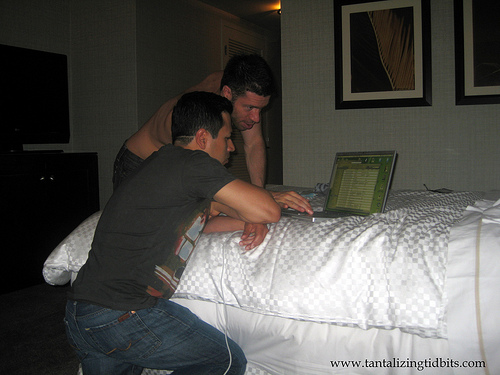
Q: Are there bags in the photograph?
A: No, there are no bags.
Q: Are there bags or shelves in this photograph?
A: No, there are no bags or shelves.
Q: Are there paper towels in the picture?
A: No, there are no paper towels.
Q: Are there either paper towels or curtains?
A: No, there are no paper towels or curtains.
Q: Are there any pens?
A: No, there are no pens.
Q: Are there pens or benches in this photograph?
A: No, there are no pens or benches.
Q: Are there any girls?
A: No, there are no girls.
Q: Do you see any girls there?
A: No, there are no girls.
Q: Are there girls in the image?
A: No, there are no girls.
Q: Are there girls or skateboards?
A: No, there are no girls or skateboards.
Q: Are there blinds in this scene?
A: No, there are no blinds.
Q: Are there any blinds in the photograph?
A: No, there are no blinds.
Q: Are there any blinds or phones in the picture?
A: No, there are no blinds or phones.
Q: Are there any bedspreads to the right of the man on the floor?
A: Yes, there is a bedspread to the right of the man.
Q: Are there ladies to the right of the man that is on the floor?
A: No, there is a bedspread to the right of the man.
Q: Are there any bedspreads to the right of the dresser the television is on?
A: Yes, there is a bedspread to the right of the dresser.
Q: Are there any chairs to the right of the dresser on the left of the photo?
A: No, there is a bedspread to the right of the dresser.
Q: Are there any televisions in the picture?
A: Yes, there is a television.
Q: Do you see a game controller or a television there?
A: Yes, there is a television.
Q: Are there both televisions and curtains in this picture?
A: No, there is a television but no curtains.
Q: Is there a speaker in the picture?
A: No, there are no speakers.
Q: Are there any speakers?
A: No, there are no speakers.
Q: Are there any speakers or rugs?
A: No, there are no speakers or rugs.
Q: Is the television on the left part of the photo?
A: Yes, the television is on the left of the image.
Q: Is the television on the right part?
A: No, the television is on the left of the image.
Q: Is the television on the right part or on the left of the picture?
A: The television is on the left of the image.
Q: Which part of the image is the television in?
A: The television is on the left of the image.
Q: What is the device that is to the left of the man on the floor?
A: The device is a television.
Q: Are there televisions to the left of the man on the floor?
A: Yes, there is a television to the left of the man.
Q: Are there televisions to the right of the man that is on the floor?
A: No, the television is to the left of the man.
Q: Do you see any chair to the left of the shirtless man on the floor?
A: No, there is a television to the left of the man.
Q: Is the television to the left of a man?
A: Yes, the television is to the left of a man.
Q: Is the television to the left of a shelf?
A: No, the television is to the left of a man.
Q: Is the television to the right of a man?
A: No, the television is to the left of a man.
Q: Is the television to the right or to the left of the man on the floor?
A: The television is to the left of the man.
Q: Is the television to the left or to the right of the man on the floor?
A: The television is to the left of the man.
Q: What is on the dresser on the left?
A: The television is on the dresser.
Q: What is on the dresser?
A: The television is on the dresser.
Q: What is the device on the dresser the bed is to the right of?
A: The device is a television.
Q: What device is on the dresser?
A: The device is a television.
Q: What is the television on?
A: The television is on the dresser.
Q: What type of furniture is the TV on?
A: The TV is on the dresser.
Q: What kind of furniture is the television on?
A: The TV is on the dresser.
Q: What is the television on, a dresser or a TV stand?
A: The television is on a dresser.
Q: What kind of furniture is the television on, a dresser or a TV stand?
A: The television is on a dresser.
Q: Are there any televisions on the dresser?
A: Yes, there is a television on the dresser.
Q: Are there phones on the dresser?
A: No, there is a television on the dresser.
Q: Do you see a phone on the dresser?
A: No, there is a television on the dresser.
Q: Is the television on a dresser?
A: Yes, the television is on a dresser.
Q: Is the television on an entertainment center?
A: No, the television is on a dresser.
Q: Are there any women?
A: No, there are no women.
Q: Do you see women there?
A: No, there are no women.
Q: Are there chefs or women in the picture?
A: No, there are no women or chefs.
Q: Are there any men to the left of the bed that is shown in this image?
A: Yes, there is a man to the left of the bed.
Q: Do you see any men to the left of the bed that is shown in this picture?
A: Yes, there is a man to the left of the bed.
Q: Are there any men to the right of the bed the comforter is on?
A: No, the man is to the left of the bed.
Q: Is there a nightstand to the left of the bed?
A: No, there is a man to the left of the bed.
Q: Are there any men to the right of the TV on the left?
A: Yes, there is a man to the right of the TV.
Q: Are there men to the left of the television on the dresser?
A: No, the man is to the right of the TV.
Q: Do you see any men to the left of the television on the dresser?
A: No, the man is to the right of the TV.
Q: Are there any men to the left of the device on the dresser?
A: No, the man is to the right of the TV.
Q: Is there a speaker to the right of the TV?
A: No, there is a man to the right of the TV.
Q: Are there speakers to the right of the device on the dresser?
A: No, there is a man to the right of the TV.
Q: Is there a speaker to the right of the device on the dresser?
A: No, there is a man to the right of the TV.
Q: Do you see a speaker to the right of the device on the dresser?
A: No, there is a man to the right of the TV.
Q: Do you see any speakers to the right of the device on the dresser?
A: No, there is a man to the right of the TV.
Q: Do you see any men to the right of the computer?
A: No, the man is to the left of the computer.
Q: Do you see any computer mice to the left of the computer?
A: No, there is a man to the left of the computer.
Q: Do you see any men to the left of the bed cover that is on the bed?
A: Yes, there is a man to the left of the quilt.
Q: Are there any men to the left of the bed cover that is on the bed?
A: Yes, there is a man to the left of the quilt.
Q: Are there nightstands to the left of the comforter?
A: No, there is a man to the left of the comforter.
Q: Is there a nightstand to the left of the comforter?
A: No, there is a man to the left of the comforter.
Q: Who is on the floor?
A: The man is on the floor.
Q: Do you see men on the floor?
A: Yes, there is a man on the floor.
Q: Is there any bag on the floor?
A: No, there is a man on the floor.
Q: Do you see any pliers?
A: No, there are no pliers.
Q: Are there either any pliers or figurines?
A: No, there are no pliers or figurines.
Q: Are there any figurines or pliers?
A: No, there are no pliers or figurines.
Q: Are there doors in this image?
A: Yes, there is a door.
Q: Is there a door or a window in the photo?
A: Yes, there is a door.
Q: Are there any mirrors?
A: No, there are no mirrors.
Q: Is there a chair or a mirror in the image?
A: No, there are no mirrors or chairs.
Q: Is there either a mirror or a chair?
A: No, there are no mirrors or chairs.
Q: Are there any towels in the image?
A: No, there are no towels.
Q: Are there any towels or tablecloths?
A: No, there are no towels or tablecloths.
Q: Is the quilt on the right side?
A: Yes, the quilt is on the right of the image.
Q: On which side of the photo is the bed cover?
A: The bed cover is on the right of the image.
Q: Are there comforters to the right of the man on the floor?
A: Yes, there is a comforter to the right of the man.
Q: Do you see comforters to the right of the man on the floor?
A: Yes, there is a comforter to the right of the man.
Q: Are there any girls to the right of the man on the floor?
A: No, there is a comforter to the right of the man.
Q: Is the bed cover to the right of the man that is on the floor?
A: Yes, the bed cover is to the right of the man.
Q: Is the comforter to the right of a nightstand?
A: No, the comforter is to the right of the man.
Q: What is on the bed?
A: The comforter is on the bed.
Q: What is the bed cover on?
A: The bed cover is on the bed.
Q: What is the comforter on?
A: The bed cover is on the bed.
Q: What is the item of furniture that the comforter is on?
A: The piece of furniture is a bed.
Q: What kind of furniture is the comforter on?
A: The comforter is on the bed.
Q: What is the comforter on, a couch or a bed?
A: The comforter is on a bed.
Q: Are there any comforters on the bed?
A: Yes, there is a comforter on the bed.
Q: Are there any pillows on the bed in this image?
A: No, there is a comforter on the bed.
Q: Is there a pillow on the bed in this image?
A: No, there is a comforter on the bed.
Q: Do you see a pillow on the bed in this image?
A: No, there is a comforter on the bed.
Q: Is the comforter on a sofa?
A: No, the comforter is on a bed.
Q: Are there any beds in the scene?
A: Yes, there is a bed.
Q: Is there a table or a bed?
A: Yes, there is a bed.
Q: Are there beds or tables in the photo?
A: Yes, there is a bed.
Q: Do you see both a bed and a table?
A: No, there is a bed but no tables.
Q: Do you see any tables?
A: No, there are no tables.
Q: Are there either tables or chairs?
A: No, there are no tables or chairs.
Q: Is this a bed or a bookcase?
A: This is a bed.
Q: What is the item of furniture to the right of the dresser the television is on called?
A: The piece of furniture is a bed.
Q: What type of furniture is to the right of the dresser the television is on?
A: The piece of furniture is a bed.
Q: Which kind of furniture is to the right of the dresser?
A: The piece of furniture is a bed.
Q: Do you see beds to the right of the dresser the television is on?
A: Yes, there is a bed to the right of the dresser.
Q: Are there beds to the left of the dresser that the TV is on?
A: No, the bed is to the right of the dresser.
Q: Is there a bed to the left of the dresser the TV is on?
A: No, the bed is to the right of the dresser.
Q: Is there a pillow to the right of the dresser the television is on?
A: No, there is a bed to the right of the dresser.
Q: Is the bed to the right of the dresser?
A: Yes, the bed is to the right of the dresser.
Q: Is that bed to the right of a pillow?
A: No, the bed is to the right of the dresser.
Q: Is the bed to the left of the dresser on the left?
A: No, the bed is to the right of the dresser.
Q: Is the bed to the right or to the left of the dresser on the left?
A: The bed is to the right of the dresser.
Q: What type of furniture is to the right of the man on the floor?
A: The piece of furniture is a bed.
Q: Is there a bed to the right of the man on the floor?
A: Yes, there is a bed to the right of the man.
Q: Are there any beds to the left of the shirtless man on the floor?
A: No, the bed is to the right of the man.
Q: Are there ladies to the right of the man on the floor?
A: No, there is a bed to the right of the man.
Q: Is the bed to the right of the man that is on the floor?
A: Yes, the bed is to the right of the man.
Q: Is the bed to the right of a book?
A: No, the bed is to the right of the man.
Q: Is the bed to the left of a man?
A: No, the bed is to the right of a man.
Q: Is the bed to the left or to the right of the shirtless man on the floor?
A: The bed is to the right of the man.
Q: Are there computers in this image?
A: Yes, there is a computer.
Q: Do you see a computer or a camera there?
A: Yes, there is a computer.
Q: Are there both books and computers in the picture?
A: No, there is a computer but no books.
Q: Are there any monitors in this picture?
A: No, there are no monitors.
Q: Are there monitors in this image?
A: No, there are no monitors.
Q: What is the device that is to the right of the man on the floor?
A: The device is a computer.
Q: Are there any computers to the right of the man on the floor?
A: Yes, there is a computer to the right of the man.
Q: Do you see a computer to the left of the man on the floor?
A: No, the computer is to the right of the man.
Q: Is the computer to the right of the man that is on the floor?
A: Yes, the computer is to the right of the man.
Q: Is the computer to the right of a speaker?
A: No, the computer is to the right of the man.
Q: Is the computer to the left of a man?
A: No, the computer is to the right of a man.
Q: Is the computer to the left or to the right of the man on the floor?
A: The computer is to the right of the man.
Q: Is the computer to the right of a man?
A: Yes, the computer is to the right of a man.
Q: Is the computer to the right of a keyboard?
A: No, the computer is to the right of a man.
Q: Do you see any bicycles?
A: No, there are no bicycles.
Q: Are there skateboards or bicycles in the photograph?
A: No, there are no bicycles or skateboards.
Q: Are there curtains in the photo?
A: No, there are no curtains.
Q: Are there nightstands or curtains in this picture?
A: No, there are no curtains or nightstands.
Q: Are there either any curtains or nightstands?
A: No, there are no curtains or nightstands.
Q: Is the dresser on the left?
A: Yes, the dresser is on the left of the image.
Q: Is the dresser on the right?
A: No, the dresser is on the left of the image.